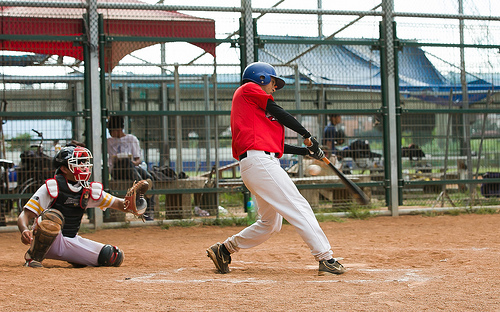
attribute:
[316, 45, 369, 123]
fence — chain-link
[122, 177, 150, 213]
mitt — brown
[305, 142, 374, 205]
bat — black and orange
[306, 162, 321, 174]
baseball — thrown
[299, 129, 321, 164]
gloves — black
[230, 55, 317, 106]
hat — black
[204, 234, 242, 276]
shoe — gray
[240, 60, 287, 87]
baseball helmet — blue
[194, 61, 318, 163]
shirt — red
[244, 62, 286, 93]
hat — blue, hard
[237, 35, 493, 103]
canopy — blue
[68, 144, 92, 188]
mask — black, red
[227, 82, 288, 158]
jersey — red